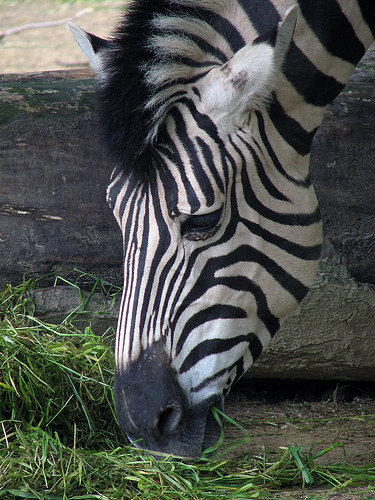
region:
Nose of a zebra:
[137, 384, 188, 441]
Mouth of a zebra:
[186, 389, 234, 486]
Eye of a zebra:
[184, 180, 233, 245]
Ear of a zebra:
[163, 5, 330, 146]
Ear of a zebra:
[57, 13, 139, 106]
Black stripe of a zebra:
[172, 297, 256, 348]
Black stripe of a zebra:
[236, 213, 356, 271]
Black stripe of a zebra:
[238, 178, 344, 230]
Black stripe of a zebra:
[261, 85, 336, 169]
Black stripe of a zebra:
[148, 191, 186, 343]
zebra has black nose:
[112, 361, 229, 470]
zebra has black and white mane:
[109, 7, 227, 163]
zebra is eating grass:
[16, 312, 168, 493]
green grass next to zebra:
[8, 307, 174, 479]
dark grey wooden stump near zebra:
[15, 59, 150, 352]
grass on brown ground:
[232, 407, 368, 497]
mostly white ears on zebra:
[185, 17, 294, 122]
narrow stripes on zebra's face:
[101, 139, 213, 394]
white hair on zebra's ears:
[208, 67, 277, 107]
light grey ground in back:
[14, 9, 105, 81]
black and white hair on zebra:
[101, 12, 290, 137]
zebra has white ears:
[196, 1, 357, 103]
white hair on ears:
[177, 53, 267, 129]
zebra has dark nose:
[85, 342, 211, 430]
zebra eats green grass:
[28, 331, 139, 461]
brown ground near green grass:
[228, 412, 358, 498]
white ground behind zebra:
[4, 3, 89, 59]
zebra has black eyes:
[169, 212, 239, 269]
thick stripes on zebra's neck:
[279, 1, 342, 140]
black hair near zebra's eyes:
[106, 69, 137, 222]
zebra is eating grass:
[97, 78, 240, 455]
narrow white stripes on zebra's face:
[93, 160, 224, 366]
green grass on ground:
[9, 307, 210, 474]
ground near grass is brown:
[239, 405, 359, 480]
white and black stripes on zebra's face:
[242, 154, 334, 342]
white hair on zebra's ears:
[202, 45, 304, 110]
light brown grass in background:
[8, 6, 81, 70]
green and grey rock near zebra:
[17, 91, 117, 272]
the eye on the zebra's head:
[173, 203, 223, 237]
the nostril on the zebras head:
[152, 401, 180, 437]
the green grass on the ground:
[3, 313, 373, 498]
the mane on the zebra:
[94, 2, 237, 185]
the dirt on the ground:
[223, 389, 366, 499]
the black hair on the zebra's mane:
[95, 89, 151, 170]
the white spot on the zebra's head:
[269, 289, 288, 312]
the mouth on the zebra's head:
[174, 401, 230, 475]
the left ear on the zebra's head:
[200, 5, 299, 132]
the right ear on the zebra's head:
[62, 18, 106, 65]